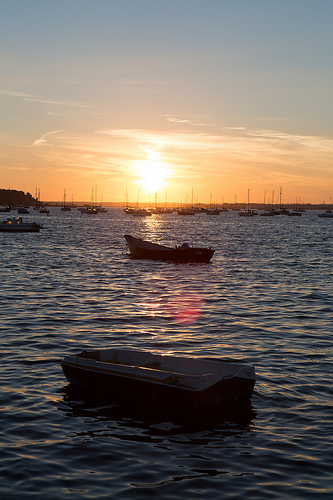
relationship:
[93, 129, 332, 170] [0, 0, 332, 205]
cloud in sky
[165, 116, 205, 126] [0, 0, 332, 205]
cloud in sky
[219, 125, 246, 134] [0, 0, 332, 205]
cloud in sky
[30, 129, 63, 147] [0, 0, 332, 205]
cloud in sky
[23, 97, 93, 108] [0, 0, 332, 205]
cloud in sky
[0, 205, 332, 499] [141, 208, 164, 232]
water has a sun reflection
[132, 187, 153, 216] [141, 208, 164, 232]
sailboat in sun reflection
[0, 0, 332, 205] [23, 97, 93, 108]
sky above cloud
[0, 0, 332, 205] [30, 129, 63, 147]
sky above cloud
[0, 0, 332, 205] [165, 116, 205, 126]
sky above cloud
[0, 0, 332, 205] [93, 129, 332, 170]
sky above cloud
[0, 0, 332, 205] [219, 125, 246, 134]
sky above cloud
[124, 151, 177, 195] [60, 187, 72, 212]
sun over sailboat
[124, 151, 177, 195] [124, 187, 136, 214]
sun over sailboat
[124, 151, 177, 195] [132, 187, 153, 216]
sun over sailboat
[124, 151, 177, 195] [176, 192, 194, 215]
sun over sailboat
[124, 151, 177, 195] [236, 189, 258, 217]
sun over sailboat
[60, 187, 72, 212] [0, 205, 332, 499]
sailboat on water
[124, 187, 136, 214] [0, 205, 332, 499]
sailboat on water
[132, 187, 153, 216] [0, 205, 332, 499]
sailboat on water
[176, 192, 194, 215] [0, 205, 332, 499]
sailboat on water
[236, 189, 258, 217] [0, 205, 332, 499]
sailboat on water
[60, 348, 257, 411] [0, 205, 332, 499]
boat floating on water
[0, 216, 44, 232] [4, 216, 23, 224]
boat has a cabin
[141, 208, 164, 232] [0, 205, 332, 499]
sun reflection on water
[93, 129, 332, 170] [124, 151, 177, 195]
cloud lit up by sun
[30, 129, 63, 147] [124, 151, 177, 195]
cloud lit up by sun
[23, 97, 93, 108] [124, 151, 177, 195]
cloud lit up by sun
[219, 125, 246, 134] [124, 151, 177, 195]
cloud lit up by sun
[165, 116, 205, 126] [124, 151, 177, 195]
cloud lit up by sun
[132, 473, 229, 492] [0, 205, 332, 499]
ripple on water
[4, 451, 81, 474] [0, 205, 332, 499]
ripple on water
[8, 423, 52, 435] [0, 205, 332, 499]
ripple on water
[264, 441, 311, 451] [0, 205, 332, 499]
ripple on water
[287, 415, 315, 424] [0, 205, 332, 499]
ripple on water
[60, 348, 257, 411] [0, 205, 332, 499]
boat in water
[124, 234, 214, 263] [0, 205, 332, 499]
boat in water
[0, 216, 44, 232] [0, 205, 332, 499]
boat in water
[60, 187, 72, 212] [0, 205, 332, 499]
sailboat in water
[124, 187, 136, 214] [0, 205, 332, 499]
sailboat in water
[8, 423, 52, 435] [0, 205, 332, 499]
ripple in water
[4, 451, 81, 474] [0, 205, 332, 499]
ripple in water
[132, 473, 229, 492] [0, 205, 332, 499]
ripple in water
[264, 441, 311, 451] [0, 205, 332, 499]
ripple in water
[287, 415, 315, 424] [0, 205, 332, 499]
ripple in water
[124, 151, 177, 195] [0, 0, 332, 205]
sun in sky